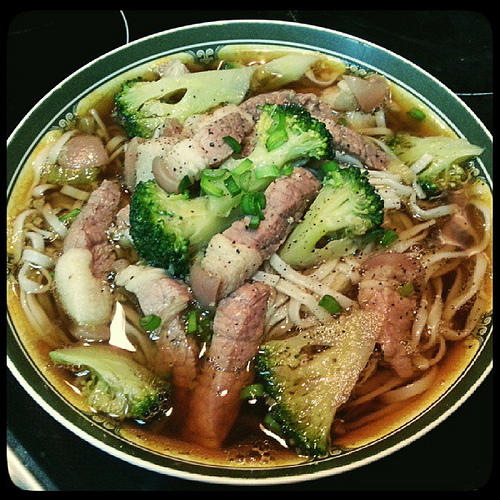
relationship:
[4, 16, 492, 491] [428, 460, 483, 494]
bowl on table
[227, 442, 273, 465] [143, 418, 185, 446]
bubbles in juice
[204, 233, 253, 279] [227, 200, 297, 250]
fat on meat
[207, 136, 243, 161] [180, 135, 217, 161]
pepper on meat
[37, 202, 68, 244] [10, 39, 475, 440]
noodles in broth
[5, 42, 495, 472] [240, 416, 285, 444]
broth has broth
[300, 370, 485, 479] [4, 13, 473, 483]
rim of bowl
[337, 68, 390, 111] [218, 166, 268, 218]
onion on center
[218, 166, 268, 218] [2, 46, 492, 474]
center of chinese food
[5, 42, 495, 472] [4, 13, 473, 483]
broth in bowl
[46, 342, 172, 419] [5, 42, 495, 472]
broccoli in broth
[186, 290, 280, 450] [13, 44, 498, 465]
steak in soup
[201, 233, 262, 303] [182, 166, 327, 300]
fat on steak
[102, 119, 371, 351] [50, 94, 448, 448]
seasoning on meat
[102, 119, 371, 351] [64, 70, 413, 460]
seasoning on vegetables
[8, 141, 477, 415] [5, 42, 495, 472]
noodles in broth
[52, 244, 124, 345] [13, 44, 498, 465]
water chestnut in soup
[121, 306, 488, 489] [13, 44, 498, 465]
broth of soup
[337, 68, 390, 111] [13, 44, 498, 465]
onion in soup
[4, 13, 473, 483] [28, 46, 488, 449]
bowl of chinese food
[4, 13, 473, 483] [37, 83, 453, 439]
bowl of beef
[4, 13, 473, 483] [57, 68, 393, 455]
bowl of broccoli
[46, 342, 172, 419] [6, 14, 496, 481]
broccoli in a dish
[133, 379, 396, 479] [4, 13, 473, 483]
sauce in a bowl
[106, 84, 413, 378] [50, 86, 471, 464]
pepper sprinkled on beef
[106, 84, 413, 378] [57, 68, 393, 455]
pepper sprinkled on broccoli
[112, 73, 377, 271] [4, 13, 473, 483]
broccoli in middle of bowl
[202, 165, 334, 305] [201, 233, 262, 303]
pork piece with fat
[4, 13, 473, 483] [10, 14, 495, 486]
bowl with rim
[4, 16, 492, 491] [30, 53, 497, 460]
bowl with noodles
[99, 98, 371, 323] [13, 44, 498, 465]
pepper sprinkled on top of soup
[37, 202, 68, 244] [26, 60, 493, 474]
noodles in broth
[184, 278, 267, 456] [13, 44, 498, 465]
meat in soup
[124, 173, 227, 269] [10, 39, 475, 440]
vegetables in broth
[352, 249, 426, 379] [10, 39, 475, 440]
meat in broth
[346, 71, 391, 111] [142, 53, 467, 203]
onion in soup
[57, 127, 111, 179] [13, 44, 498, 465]
mushroom in soup